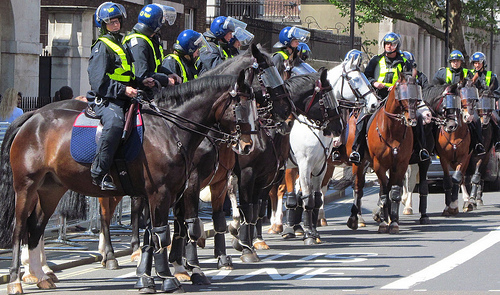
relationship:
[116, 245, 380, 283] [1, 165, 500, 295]
paint on street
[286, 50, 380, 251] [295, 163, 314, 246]
horse has a leg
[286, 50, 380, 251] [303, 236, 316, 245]
horse has a hoof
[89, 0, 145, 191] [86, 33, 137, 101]
man wearing a jacket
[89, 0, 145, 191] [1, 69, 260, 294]
man on a horse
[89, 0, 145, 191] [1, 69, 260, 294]
man riding a horse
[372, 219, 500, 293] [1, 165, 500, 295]
line painted on street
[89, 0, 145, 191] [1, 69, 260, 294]
man sitting on a horse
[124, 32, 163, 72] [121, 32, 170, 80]
stripe on vest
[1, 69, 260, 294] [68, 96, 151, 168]
horse wearing a saddle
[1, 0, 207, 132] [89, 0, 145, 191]
building behind man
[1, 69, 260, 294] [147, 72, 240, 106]
horse has a mane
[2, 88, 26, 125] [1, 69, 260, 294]
person behind horse